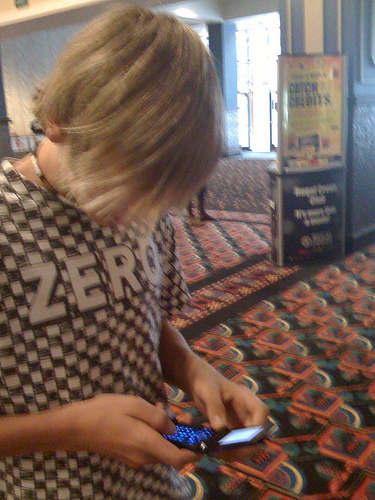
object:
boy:
[0, 3, 270, 498]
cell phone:
[156, 417, 269, 456]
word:
[17, 234, 164, 327]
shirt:
[0, 156, 190, 499]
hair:
[33, 3, 228, 247]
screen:
[214, 425, 264, 446]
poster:
[276, 56, 349, 268]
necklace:
[28, 138, 80, 208]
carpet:
[163, 157, 374, 499]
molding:
[205, 19, 240, 158]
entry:
[234, 11, 280, 156]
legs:
[195, 188, 208, 213]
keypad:
[162, 421, 215, 446]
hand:
[83, 392, 205, 471]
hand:
[188, 366, 269, 464]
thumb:
[201, 388, 227, 433]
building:
[0, 0, 374, 498]